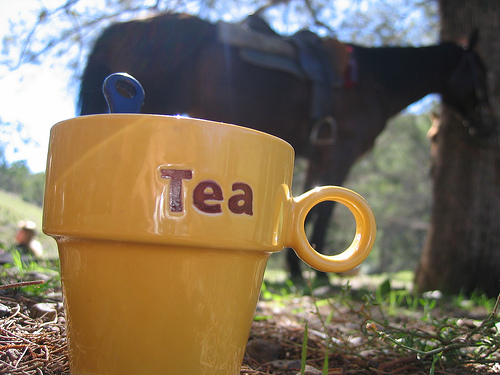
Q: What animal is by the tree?
A: A horse.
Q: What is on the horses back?
A: A saddle.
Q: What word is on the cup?
A: Tea.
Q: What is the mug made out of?
A: Ceramics.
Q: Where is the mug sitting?
A: On the ground.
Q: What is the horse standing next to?
A: A tree.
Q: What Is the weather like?
A: Sunny and clear.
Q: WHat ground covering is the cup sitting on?
A: Pine straw.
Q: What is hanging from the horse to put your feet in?
A: Stirrups.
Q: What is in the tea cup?
A: A blue spoon.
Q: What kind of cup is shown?
A: Tea cup.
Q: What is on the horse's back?
A: Saddle.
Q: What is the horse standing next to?
A: Tree.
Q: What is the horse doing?
A: Standing.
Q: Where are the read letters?
A: On the mug.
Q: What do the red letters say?
A: Tea.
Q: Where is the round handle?
A: On the mug.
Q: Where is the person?
A: Behind the horse to the right.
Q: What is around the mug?
A: Grass and twigs.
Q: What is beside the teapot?
A: Horse.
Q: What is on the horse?
A: A saddle.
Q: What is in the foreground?
A: A mug.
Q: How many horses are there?
A: One.